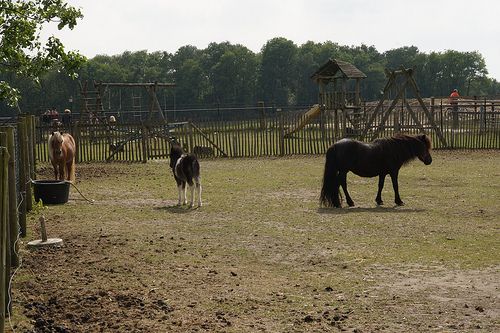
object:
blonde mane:
[48, 131, 77, 182]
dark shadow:
[317, 203, 433, 214]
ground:
[12, 150, 499, 333]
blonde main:
[48, 131, 77, 185]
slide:
[280, 104, 321, 137]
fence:
[36, 113, 500, 164]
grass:
[21, 160, 500, 333]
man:
[450, 89, 462, 106]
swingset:
[88, 82, 177, 144]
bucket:
[34, 179, 70, 204]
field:
[0, 169, 500, 333]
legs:
[175, 170, 202, 208]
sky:
[85, 0, 500, 57]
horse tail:
[317, 145, 340, 208]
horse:
[318, 134, 433, 207]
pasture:
[0, 153, 500, 333]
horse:
[168, 140, 203, 208]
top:
[450, 93, 459, 103]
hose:
[35, 163, 55, 180]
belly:
[349, 168, 382, 178]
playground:
[285, 95, 446, 150]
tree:
[430, 49, 485, 100]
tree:
[388, 38, 419, 95]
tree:
[335, 41, 388, 103]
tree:
[256, 37, 303, 116]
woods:
[46, 39, 490, 119]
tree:
[114, 49, 176, 112]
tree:
[39, 51, 88, 114]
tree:
[31, 50, 86, 111]